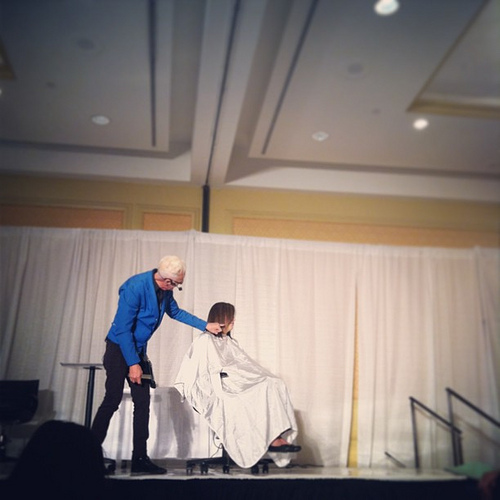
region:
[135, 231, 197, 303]
The main is wearing a headset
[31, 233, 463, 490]
The people are on a stage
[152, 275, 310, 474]
The woman is in a chair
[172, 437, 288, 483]
The chair is on wheels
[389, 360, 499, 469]
There are stairs up to the stage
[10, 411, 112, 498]
Back of a person's head in the audience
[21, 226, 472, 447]
White curtain lining the back of the stage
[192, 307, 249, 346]
Man's left hand near woman's face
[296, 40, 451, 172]
Some, but not all of the lights are on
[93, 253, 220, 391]
Man is wearing a blue cardigan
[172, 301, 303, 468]
a woman wearing a white cape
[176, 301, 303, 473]
a woman in a white cap sitting in a hair salon chair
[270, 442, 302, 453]
a black flat shoe under the white cape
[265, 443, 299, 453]
black shoes on the woman's feet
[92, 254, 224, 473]
a hairstylist speaking to an audience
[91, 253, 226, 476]
a man styling a woman's hair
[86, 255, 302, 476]
a woman in a cape and a male hairstylist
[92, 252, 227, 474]
a male hairstylist in a blue blazer pointing to the woman's hair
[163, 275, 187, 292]
a headset with microphone on the hairstylist's ear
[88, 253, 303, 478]
a hairstylist with blonde hair and a woman in a white cape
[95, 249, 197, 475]
Man giving a haircut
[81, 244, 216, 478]
Man demonstrating how to cut air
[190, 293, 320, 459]
Girl getting her hair cut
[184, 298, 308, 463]
Girl volunteering for a haircut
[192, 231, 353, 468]
Drapes serving as a background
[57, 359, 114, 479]
Small table on the stage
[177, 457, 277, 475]
Wheels on a swivel chair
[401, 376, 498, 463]
Rails or a small stair case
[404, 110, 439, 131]
Overhead lighting built into the ceiling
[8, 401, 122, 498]
Person sitting in the row in front of the photographer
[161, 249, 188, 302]
a microphone attached to man's ear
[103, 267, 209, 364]
man wears a blue sweater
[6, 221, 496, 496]
white drapes camouflage the wall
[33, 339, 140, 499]
Pedestal table on a stage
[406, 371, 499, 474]
hand railings flank the stairs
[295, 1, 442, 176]
inset ceiling lights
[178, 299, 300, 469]
woman having her hair worked with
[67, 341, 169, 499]
black slacks with black shoes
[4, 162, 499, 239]
golden trim on orange wall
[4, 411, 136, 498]
the back of spectators head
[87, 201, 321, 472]
Barber cutting hair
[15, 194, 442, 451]
scene of a play of a barber cutting hair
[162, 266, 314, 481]
person getting a pretend haircut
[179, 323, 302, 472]
white drop cloth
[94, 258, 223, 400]
vibrant blue sweater on barber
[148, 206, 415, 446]
white curtains in front of a wall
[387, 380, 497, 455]
rails to back stage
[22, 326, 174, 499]
small waist-high table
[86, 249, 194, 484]
barber wearing blue sweater and black jeans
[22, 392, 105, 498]
the back of the head of a member in the audience